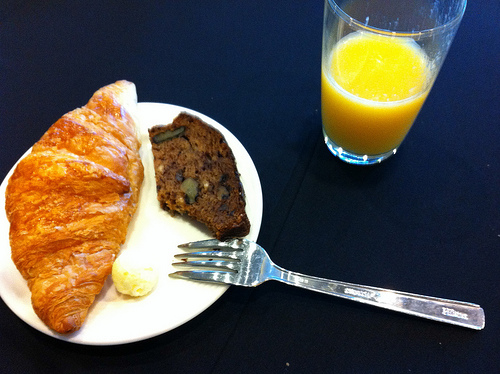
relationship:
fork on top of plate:
[182, 236, 476, 334] [132, 98, 167, 111]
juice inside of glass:
[316, 27, 423, 152] [327, 134, 426, 168]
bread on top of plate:
[6, 79, 144, 337] [132, 98, 167, 111]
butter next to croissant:
[118, 238, 158, 308] [98, 71, 142, 138]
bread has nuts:
[42, 94, 118, 280] [59, 184, 122, 217]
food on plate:
[8, 79, 241, 300] [132, 98, 167, 111]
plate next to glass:
[132, 98, 167, 111] [327, 134, 426, 168]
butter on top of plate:
[118, 238, 158, 308] [132, 98, 167, 111]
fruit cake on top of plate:
[221, 216, 245, 226] [132, 98, 167, 111]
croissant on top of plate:
[98, 71, 142, 138] [132, 98, 167, 111]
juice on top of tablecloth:
[316, 27, 423, 152] [166, 35, 246, 66]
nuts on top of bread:
[59, 184, 122, 217] [42, 94, 118, 280]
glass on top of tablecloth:
[327, 134, 426, 168] [166, 35, 246, 66]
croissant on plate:
[98, 71, 142, 138] [132, 98, 167, 111]